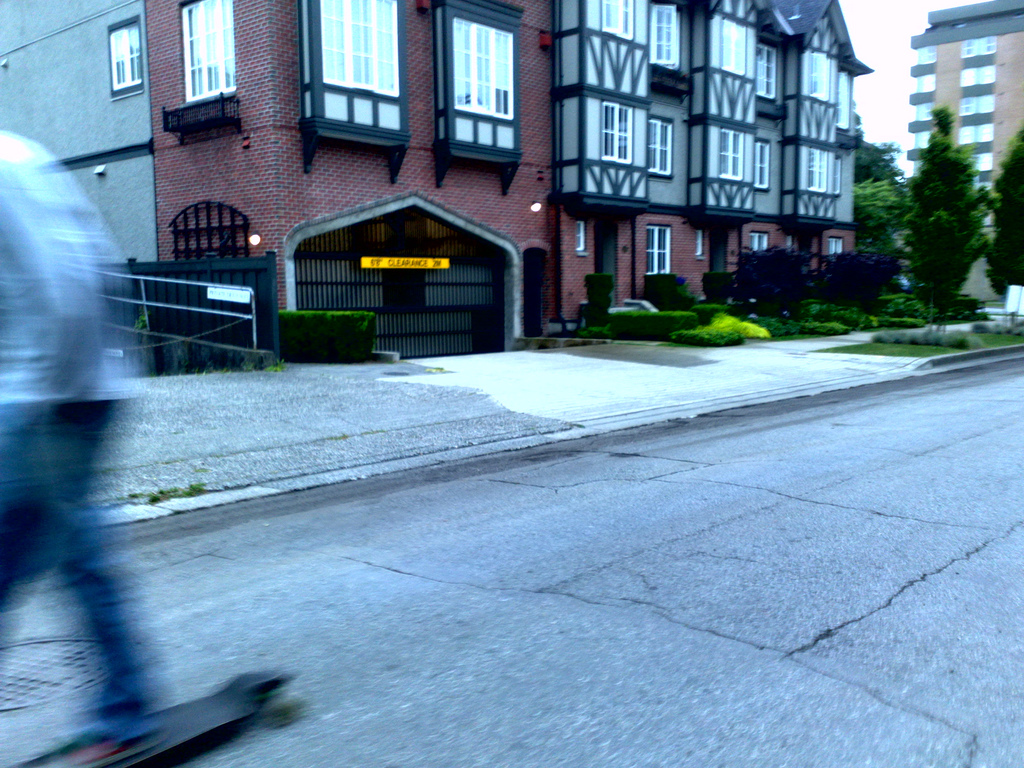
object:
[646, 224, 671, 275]
window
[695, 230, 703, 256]
window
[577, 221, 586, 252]
window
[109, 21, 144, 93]
window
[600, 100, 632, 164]
window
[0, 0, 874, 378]
building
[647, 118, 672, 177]
window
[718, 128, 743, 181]
window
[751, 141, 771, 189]
window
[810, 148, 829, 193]
window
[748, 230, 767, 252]
window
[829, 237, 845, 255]
window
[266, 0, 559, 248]
wall